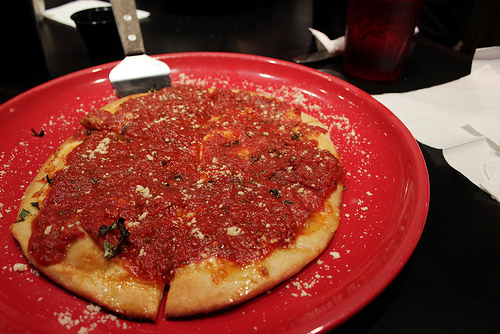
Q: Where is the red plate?
A: Beneath pizza.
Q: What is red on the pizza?
A: Sauce.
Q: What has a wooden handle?
A: Spatula.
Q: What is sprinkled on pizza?
A: Cheese.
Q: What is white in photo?
A: Napkin.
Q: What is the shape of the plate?
A: Round.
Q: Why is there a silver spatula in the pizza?
A: For serving.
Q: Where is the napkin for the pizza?
A: Next to the red plate.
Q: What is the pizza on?
A: A red plate.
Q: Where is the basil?
A: Sprinkled on top of the pizza.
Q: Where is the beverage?
A: Behind the red plate.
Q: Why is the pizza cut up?
A: To be served.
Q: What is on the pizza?
A: Red sauce.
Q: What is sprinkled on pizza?
A: Cheese.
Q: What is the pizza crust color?
A: Golden.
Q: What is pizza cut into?
A: Slices.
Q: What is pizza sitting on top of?
A: Red plate.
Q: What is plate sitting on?
A: Black table.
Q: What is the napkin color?
A: White.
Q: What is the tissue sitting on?
A: Table.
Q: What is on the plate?
A: A pizza.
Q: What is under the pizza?
A: A spatula.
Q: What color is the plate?
A: Red.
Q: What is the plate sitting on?
A: A table.